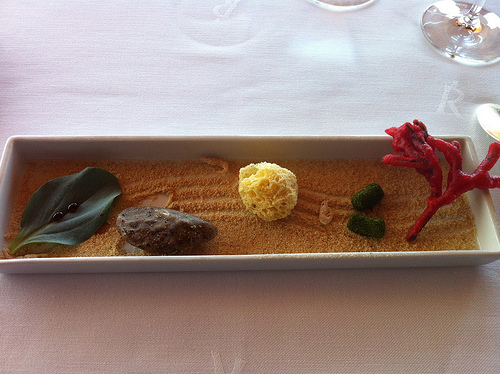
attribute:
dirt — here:
[165, 172, 217, 209]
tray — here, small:
[12, 114, 500, 275]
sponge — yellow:
[233, 158, 320, 220]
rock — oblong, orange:
[121, 200, 227, 249]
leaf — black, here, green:
[18, 161, 130, 246]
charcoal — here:
[47, 198, 88, 223]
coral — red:
[382, 111, 495, 250]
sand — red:
[309, 169, 351, 196]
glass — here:
[420, 2, 498, 74]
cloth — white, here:
[94, 19, 261, 86]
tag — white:
[34, 32, 86, 88]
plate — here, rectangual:
[188, 2, 269, 49]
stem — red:
[420, 199, 451, 241]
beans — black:
[57, 202, 92, 231]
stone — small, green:
[315, 188, 340, 229]